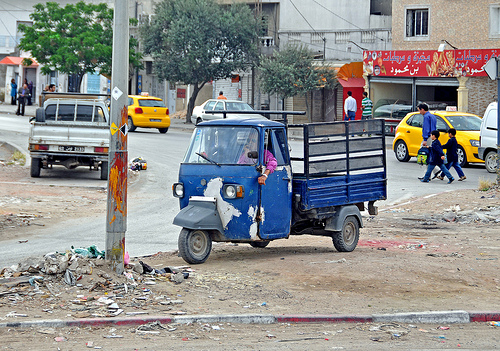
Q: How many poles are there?
A: One.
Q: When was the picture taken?
A: Daytime.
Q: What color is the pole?
A: Gray.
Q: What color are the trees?
A: Green.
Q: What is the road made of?
A: Asphalt.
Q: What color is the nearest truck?
A: Blue.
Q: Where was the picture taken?
A: On a road.